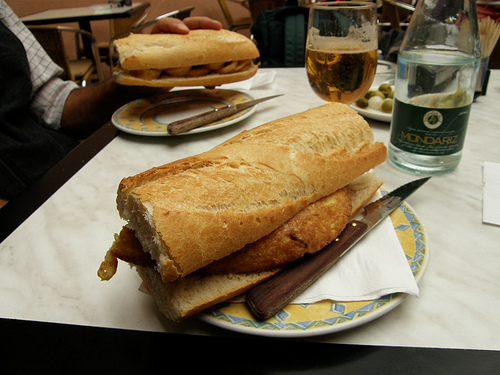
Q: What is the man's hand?
A: A sub sandwich.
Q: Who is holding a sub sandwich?
A: A man.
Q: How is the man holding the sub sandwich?
A: In the left hand.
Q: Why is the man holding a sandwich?
A: To eat for lunch.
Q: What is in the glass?
A: Champagne.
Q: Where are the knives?
A: On plates.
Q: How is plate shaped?
A: Round.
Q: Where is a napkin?
A: Under sandwich.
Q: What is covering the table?
A: White paper.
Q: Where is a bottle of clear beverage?
A: To right of sandwich.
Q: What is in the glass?
A: Amber beverage.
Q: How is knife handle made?
A: With wood.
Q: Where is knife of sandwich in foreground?
A: On plate.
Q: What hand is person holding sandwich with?
A: Left.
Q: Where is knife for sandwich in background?
A: On plate.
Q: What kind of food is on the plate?
A: A sandwich.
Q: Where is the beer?
A: In a glass.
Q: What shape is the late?
A: Round.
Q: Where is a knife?
A: On plate.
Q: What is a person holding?
A: A sandwich.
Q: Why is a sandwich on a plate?
A: To be eaten.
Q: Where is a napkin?
A: On the plate.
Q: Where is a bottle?
A: In the middle of the table.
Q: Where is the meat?
A: In the sandwich.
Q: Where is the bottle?
A: Next to the glass.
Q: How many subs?
A: Two.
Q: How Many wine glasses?
A: One.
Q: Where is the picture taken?
A: Restaurant.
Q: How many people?
A: One.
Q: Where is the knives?
A: On the plates.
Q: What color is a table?
A: White.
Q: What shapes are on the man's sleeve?
A: Square.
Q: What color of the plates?
A: Blue, yellow and white.